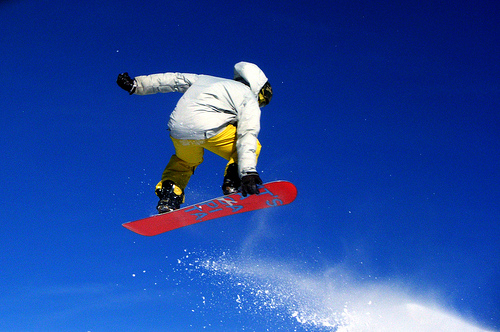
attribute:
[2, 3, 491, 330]
sky — blue, clear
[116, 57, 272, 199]
person — snowboarding, pictured, in midair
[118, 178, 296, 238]
snowboard — red, blue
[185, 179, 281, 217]
graphics — blue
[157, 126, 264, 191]
pants — yellow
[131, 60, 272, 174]
jacket — light grey, silver, hooded, grey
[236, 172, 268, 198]
glove — black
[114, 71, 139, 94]
glove — black, on left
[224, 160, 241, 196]
boot — black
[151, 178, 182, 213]
boot — black, snow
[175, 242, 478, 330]
snow — flying, white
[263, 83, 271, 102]
goggles — yellow